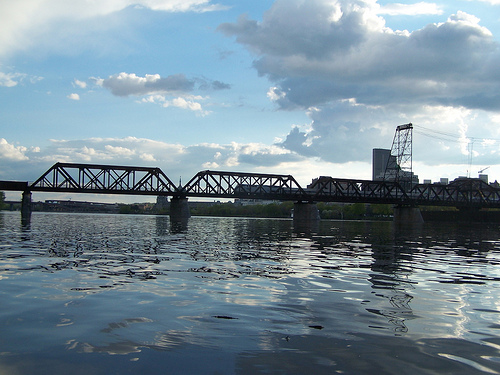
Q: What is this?
A: Bridge.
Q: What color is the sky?
A: Blue.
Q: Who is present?
A: No one.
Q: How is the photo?
A: Clear.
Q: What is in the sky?
A: Clouds.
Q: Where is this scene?
A: By the Harrisburg bridge.